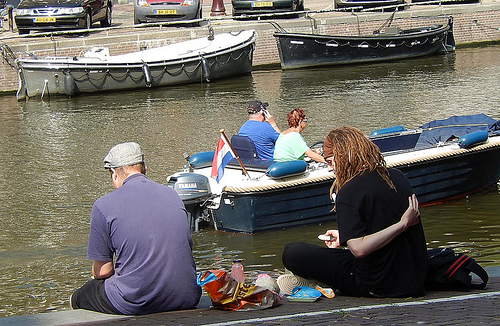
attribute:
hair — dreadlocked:
[320, 122, 396, 197]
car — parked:
[12, 0, 114, 38]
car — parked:
[131, 0, 203, 26]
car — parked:
[229, 0, 305, 21]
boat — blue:
[163, 112, 498, 239]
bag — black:
[421, 241, 475, 281]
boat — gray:
[6, 23, 262, 93]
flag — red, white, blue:
[198, 136, 242, 183]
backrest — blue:
[223, 135, 262, 157]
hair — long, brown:
[314, 125, 401, 188]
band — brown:
[314, 135, 334, 157]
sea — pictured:
[8, 102, 103, 255]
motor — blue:
[161, 175, 218, 215]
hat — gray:
[94, 139, 150, 169]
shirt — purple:
[81, 179, 202, 309]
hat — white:
[97, 141, 144, 166]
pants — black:
[65, 275, 122, 312]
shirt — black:
[332, 180, 439, 295]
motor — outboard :
[163, 176, 229, 234]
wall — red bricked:
[457, 17, 484, 40]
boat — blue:
[162, 137, 493, 235]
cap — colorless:
[98, 140, 154, 172]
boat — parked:
[1, 27, 259, 97]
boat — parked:
[275, 18, 461, 68]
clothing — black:
[282, 168, 427, 298]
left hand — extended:
[343, 190, 424, 259]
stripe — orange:
[444, 251, 464, 271]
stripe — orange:
[450, 257, 469, 277]